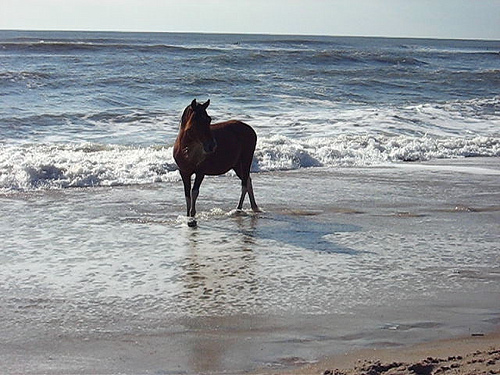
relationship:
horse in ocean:
[163, 93, 273, 218] [2, 29, 499, 285]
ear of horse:
[199, 90, 215, 112] [162, 91, 265, 225]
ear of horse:
[190, 96, 197, 113] [162, 91, 265, 225]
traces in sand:
[371, 339, 451, 371] [404, 324, 475, 364]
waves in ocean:
[0, 98, 499, 189] [317, 111, 409, 251]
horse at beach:
[163, 93, 273, 218] [180, 260, 303, 291]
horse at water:
[163, 93, 273, 218] [106, 228, 213, 278]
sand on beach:
[326, 324, 398, 355] [364, 347, 456, 373]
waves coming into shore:
[287, 103, 377, 174] [278, 183, 387, 272]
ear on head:
[182, 96, 197, 113] [155, 89, 221, 177]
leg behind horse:
[228, 169, 268, 211] [109, 80, 319, 248]